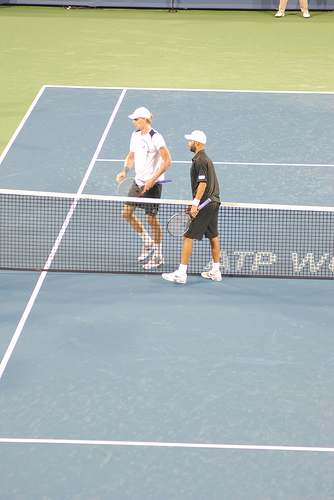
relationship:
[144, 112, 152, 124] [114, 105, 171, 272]
hair on man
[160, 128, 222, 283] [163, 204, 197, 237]
man with racket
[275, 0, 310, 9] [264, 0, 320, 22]
legs of onlooker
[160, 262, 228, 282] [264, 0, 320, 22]
feet of onlooker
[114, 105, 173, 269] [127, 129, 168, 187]
man wearing shirt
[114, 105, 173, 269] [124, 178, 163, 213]
man wearing black shorts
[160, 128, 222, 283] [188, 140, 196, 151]
man with beard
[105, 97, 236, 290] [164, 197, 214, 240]
both holding racket